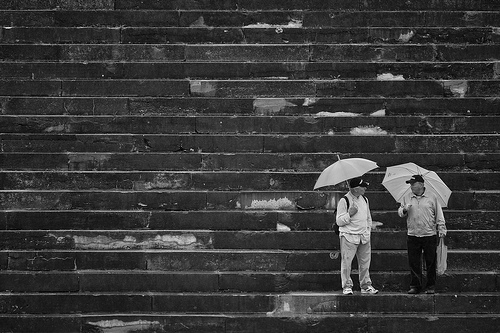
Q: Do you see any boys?
A: No, there are no boys.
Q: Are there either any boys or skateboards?
A: No, there are no boys or skateboards.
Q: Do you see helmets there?
A: No, there are no helmets.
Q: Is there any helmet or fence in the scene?
A: No, there are no helmets or fences.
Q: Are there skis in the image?
A: No, there are no skis.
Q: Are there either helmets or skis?
A: No, there are no skis or helmets.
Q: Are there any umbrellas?
A: Yes, there is an umbrella.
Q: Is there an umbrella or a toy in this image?
A: Yes, there is an umbrella.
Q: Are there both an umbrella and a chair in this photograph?
A: No, there is an umbrella but no chairs.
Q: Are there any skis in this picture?
A: No, there are no skis.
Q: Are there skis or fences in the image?
A: No, there are no skis or fences.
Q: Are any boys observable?
A: No, there are no boys.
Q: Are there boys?
A: No, there are no boys.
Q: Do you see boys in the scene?
A: No, there are no boys.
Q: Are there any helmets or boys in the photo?
A: No, there are no boys or helmets.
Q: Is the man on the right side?
A: Yes, the man is on the right of the image.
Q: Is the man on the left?
A: No, the man is on the right of the image.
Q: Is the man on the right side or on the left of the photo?
A: The man is on the right of the image.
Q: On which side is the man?
A: The man is on the right of the image.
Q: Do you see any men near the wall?
A: Yes, there is a man near the wall.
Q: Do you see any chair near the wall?
A: No, there is a man near the wall.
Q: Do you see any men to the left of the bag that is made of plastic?
A: Yes, there is a man to the left of the bag.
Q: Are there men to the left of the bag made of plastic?
A: Yes, there is a man to the left of the bag.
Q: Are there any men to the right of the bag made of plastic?
A: No, the man is to the left of the bag.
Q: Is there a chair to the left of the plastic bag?
A: No, there is a man to the left of the bag.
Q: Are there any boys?
A: No, there are no boys.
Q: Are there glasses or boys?
A: No, there are no boys or glasses.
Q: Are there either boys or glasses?
A: No, there are no boys or glasses.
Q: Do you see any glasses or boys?
A: No, there are no boys or glasses.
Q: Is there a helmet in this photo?
A: No, there are no helmets.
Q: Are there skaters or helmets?
A: No, there are no helmets or skaters.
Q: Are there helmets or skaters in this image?
A: No, there are no helmets or skaters.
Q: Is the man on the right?
A: Yes, the man is on the right of the image.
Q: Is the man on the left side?
A: No, the man is on the right of the image.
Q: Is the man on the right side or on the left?
A: The man is on the right of the image.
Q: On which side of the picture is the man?
A: The man is on the right of the image.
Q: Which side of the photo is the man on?
A: The man is on the right of the image.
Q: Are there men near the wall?
A: Yes, there is a man near the wall.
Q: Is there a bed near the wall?
A: No, there is a man near the wall.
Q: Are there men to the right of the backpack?
A: Yes, there is a man to the right of the backpack.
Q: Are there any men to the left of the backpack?
A: No, the man is to the right of the backpack.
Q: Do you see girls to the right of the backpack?
A: No, there is a man to the right of the backpack.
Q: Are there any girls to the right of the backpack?
A: No, there is a man to the right of the backpack.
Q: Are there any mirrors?
A: No, there are no mirrors.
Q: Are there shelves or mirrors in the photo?
A: No, there are no mirrors or shelves.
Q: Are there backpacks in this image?
A: Yes, there is a backpack.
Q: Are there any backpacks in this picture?
A: Yes, there is a backpack.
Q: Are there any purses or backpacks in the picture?
A: Yes, there is a backpack.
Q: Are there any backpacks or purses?
A: Yes, there is a backpack.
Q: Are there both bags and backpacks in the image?
A: Yes, there are both a backpack and a bag.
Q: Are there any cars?
A: No, there are no cars.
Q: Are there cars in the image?
A: No, there are no cars.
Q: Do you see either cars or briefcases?
A: No, there are no cars or briefcases.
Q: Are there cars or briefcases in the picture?
A: No, there are no cars or briefcases.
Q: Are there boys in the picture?
A: No, there are no boys.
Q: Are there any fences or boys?
A: No, there are no boys or fences.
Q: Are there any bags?
A: Yes, there is a bag.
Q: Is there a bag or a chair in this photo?
A: Yes, there is a bag.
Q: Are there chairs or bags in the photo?
A: Yes, there is a bag.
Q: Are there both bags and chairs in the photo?
A: No, there is a bag but no chairs.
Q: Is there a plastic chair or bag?
A: Yes, there is a plastic bag.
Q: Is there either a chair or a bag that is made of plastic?
A: Yes, the bag is made of plastic.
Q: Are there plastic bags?
A: Yes, there is a bag that is made of plastic.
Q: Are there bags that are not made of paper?
A: Yes, there is a bag that is made of plastic.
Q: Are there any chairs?
A: No, there are no chairs.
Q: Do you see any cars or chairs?
A: No, there are no chairs or cars.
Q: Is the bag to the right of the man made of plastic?
A: Yes, the bag is made of plastic.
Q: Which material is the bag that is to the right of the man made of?
A: The bag is made of plastic.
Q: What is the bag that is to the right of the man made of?
A: The bag is made of plastic.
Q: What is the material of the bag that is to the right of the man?
A: The bag is made of plastic.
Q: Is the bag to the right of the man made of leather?
A: No, the bag is made of plastic.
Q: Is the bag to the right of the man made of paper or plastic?
A: The bag is made of plastic.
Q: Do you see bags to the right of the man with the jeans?
A: Yes, there is a bag to the right of the man.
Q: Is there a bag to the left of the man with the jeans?
A: No, the bag is to the right of the man.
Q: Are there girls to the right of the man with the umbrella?
A: No, there is a bag to the right of the man.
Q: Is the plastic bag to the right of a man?
A: Yes, the bag is to the right of a man.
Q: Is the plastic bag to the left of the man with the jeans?
A: No, the bag is to the right of the man.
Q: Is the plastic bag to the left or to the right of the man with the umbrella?
A: The bag is to the right of the man.